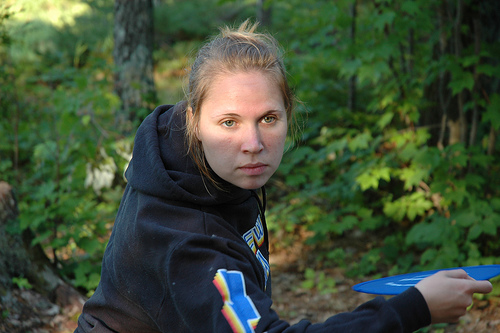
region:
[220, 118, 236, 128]
the intensely concentrated blue eye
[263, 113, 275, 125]
the intensely concentrated blue eye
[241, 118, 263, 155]
the nose on a face of a woman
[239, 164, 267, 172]
the mouth on a face of a woman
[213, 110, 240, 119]
the eyebrow on a face of a woman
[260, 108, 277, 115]
the eyebrow on a face of a woman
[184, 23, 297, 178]
the blondish hair of a woman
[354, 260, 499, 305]
a blue and white frisbee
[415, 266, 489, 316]
a woman's hand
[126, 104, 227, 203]
the black hood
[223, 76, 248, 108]
head of a lady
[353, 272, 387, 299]
edge of a dish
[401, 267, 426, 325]
edge of a sleeve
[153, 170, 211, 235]
edge of a hood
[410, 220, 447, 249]
part of some leaf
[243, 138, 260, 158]
part of a nose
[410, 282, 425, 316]
part of a dish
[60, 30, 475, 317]
A girl with a frisbee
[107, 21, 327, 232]
A girl with a serious expression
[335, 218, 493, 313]
A blue frisbee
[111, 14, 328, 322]
A girl with a blue shirt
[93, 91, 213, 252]
The hood on a shirt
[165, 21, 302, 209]
the head of a girl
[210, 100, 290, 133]
the eye of a girl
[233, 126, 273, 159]
the nose of a girl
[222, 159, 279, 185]
the mouth of a girl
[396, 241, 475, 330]
the hand of a girl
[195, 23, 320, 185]
woman looking past the camera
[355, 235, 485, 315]
Frisbee in lady's hand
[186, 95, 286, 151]
eyes of the lady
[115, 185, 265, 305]
jacket of the lady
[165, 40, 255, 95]
brown hair of the lady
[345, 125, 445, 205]
green leaves behind lady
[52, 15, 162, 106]
trunk of a tree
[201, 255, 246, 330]
blue, yellow and orange sleeve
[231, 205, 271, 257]
writing on front of jacket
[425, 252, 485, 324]
woman's hand holding a Frisbee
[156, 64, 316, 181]
sunlight on woman's face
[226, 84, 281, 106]
faint lines across woman's face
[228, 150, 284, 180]
red lipstick on woman's face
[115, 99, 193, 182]
gray hoodie on jacket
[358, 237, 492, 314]
blue frisbee in woman's hand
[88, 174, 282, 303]
woman wearing blue jacket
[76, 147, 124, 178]
small cluster of white leaves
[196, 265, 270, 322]
orange and blue symbol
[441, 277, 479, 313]
veins in woman's hand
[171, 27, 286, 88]
blond hair on woman's head